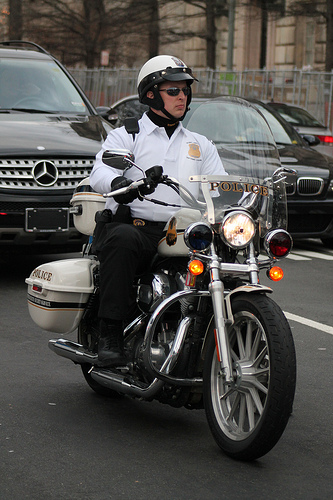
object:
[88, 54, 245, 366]
police officer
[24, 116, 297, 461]
motorcycle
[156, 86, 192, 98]
sun glasses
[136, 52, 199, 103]
helmet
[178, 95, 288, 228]
windshield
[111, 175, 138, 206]
glove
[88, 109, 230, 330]
uniform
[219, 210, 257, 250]
headlight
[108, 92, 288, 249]
car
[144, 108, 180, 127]
turtleneck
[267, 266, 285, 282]
light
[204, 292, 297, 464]
wheel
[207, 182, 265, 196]
decal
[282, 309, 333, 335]
white paint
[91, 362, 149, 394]
foot rest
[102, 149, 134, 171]
rearview mirror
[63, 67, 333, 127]
fence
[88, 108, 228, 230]
shirt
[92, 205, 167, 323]
pants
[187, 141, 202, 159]
shield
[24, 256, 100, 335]
tank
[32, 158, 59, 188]
logo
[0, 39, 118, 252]
suv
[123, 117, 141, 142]
radio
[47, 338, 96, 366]
muffler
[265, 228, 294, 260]
emergency light